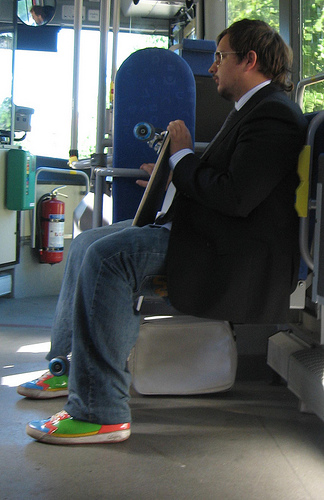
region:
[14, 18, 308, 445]
Man with skateboard sitting in bus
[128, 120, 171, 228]
Skateboard resting in man's lap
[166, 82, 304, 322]
Dark coat on man on bus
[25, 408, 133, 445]
Colorful shoe on man on bus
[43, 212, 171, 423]
Blue jeans on man on bus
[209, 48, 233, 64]
Glasses on man on bus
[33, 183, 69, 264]
Red fire extinguisher on bus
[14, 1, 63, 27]
Mirror on bus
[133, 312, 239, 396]
White case under seat of man on bus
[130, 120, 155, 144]
Blue wheel on skateboard held by man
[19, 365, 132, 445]
the man's colorful shoes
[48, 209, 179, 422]
the man's denim jeans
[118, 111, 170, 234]
the skateboard the man is holding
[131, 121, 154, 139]
the wheels on the skateboard near the man's hand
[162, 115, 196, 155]
the man's hand on the skateboard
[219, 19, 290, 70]
the dark hair on the man's head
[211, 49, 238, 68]
the glasses on the man's face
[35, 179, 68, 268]
the red fire extinguisher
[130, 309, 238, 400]
the white object under the man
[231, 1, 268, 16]
the trees outside of the window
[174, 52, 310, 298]
man sitting on bus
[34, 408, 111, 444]
man wearing colorful sneakers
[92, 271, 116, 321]
man wearing blue jeans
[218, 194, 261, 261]
man wearing black jacket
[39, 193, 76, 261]
fire extinguisher on bus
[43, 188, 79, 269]
fire extinguisher is red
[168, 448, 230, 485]
floor of bus is gray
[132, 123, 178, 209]
man holding black skateboard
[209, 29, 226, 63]
man wearing brown sunglasses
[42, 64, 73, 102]
windshield of big bus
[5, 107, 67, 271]
Fire extinguisher mounted on a bus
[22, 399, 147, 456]
Red, green, yellow and blue sneaker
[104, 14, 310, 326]
Man on a bus holding a skateboard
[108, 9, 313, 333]
Man riding a bus in a sport's coat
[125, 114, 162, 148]
Blue skateboard wheel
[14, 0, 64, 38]
Bus mirror showing a man's face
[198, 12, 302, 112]
Brown haired male wearing glasses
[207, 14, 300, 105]
Dark brown haired guy wearing glasses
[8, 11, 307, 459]
Guy in jeans and a sport jacket holding a skateboard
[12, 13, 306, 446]
Guy wearing blue jeans holding a skateboard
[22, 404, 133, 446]
orange, green, blue, and white shoes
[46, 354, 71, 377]
blue wheel of skateboard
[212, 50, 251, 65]
glasses worn by man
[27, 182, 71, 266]
red emergency fire extinguisher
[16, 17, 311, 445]
man holding a skateboard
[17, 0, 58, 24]
reflection of man in mirror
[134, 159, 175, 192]
man's hand on rail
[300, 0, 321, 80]
leaves on trees out the window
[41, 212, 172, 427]
blue jeans worn by man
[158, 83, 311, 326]
man's black sport coat